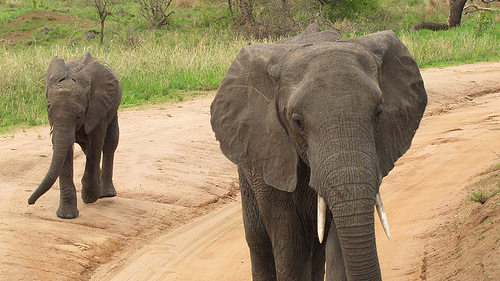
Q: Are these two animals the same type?
A: Yes, all the animals are elephants.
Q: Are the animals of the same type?
A: Yes, all the animals are elephants.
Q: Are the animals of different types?
A: No, all the animals are elephants.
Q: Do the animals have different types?
A: No, all the animals are elephants.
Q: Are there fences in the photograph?
A: No, there are no fences.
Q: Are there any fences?
A: No, there are no fences.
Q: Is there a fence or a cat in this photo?
A: No, there are no fences or cats.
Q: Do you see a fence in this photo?
A: No, there are no fences.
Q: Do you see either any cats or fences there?
A: No, there are no fences or cats.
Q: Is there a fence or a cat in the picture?
A: No, there are no fences or cats.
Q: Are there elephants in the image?
A: Yes, there is an elephant.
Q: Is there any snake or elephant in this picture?
A: Yes, there is an elephant.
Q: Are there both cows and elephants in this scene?
A: No, there is an elephant but no cows.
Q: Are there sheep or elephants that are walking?
A: Yes, the elephant is walking.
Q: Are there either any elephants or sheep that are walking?
A: Yes, the elephant is walking.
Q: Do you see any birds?
A: No, there are no birds.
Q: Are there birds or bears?
A: No, there are no birds or bears.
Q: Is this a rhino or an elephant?
A: This is an elephant.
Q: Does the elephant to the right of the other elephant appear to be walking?
A: Yes, the elephant is walking.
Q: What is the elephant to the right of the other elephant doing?
A: The elephant is walking.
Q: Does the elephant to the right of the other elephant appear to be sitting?
A: No, the elephant is walking.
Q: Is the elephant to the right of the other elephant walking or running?
A: The elephant is walking.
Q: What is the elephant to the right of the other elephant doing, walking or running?
A: The elephant is walking.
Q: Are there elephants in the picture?
A: Yes, there is an elephant.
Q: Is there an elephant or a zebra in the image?
A: Yes, there is an elephant.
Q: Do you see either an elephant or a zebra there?
A: Yes, there is an elephant.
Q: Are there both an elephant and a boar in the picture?
A: No, there is an elephant but no boars.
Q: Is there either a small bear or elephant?
A: Yes, there is a small elephant.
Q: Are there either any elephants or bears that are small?
A: Yes, the elephant is small.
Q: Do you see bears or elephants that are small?
A: Yes, the elephant is small.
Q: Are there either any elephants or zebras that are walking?
A: Yes, the elephant is walking.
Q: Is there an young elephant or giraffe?
A: Yes, there is a young elephant.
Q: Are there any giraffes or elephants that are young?
A: Yes, the elephant is young.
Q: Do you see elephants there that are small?
A: Yes, there is a small elephant.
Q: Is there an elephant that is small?
A: Yes, there is an elephant that is small.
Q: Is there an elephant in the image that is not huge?
A: Yes, there is a small elephant.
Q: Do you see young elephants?
A: Yes, there is a young elephant.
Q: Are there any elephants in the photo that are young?
A: Yes, there is an elephant that is young.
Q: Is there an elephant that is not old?
A: Yes, there is an young elephant.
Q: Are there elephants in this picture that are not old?
A: Yes, there is an young elephant.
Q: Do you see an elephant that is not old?
A: Yes, there is an young elephant.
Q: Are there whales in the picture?
A: No, there are no whales.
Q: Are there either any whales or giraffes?
A: No, there are no whales or giraffes.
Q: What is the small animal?
A: The animal is an elephant.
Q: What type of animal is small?
A: The animal is an elephant.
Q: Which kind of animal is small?
A: The animal is an elephant.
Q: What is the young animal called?
A: The animal is an elephant.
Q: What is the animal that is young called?
A: The animal is an elephant.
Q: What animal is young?
A: The animal is an elephant.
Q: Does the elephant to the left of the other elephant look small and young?
A: Yes, the elephant is small and young.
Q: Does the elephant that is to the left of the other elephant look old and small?
A: No, the elephant is small but young.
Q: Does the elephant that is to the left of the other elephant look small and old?
A: No, the elephant is small but young.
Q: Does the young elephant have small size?
A: Yes, the elephant is small.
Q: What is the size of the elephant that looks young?
A: The elephant is small.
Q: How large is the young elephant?
A: The elephant is small.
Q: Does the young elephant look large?
A: No, the elephant is small.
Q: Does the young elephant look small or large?
A: The elephant is small.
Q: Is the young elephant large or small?
A: The elephant is small.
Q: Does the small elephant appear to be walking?
A: Yes, the elephant is walking.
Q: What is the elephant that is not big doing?
A: The elephant is walking.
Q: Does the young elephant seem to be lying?
A: No, the elephant is walking.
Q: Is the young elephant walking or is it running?
A: The elephant is walking.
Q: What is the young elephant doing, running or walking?
A: The elephant is walking.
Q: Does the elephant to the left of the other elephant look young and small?
A: Yes, the elephant is young and small.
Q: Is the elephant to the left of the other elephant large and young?
A: No, the elephant is young but small.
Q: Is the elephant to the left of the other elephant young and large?
A: No, the elephant is young but small.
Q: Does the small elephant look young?
A: Yes, the elephant is young.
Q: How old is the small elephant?
A: The elephant is young.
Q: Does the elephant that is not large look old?
A: No, the elephant is young.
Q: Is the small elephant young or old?
A: The elephant is young.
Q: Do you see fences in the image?
A: No, there are no fences.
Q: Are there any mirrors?
A: No, there are no mirrors.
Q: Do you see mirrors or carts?
A: No, there are no mirrors or carts.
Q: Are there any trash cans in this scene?
A: No, there are no trash cans.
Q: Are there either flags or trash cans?
A: No, there are no trash cans or flags.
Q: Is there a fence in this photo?
A: No, there are no fences.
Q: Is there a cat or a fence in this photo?
A: No, there are no fences or cats.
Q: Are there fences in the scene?
A: No, there are no fences.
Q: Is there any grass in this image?
A: Yes, there is grass.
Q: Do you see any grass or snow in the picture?
A: Yes, there is grass.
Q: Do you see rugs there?
A: No, there are no rugs.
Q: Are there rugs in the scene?
A: No, there are no rugs.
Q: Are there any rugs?
A: No, there are no rugs.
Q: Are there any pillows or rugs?
A: No, there are no rugs or pillows.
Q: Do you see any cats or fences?
A: No, there are no fences or cats.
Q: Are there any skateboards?
A: No, there are no skateboards.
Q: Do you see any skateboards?
A: No, there are no skateboards.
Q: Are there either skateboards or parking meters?
A: No, there are no skateboards or parking meters.